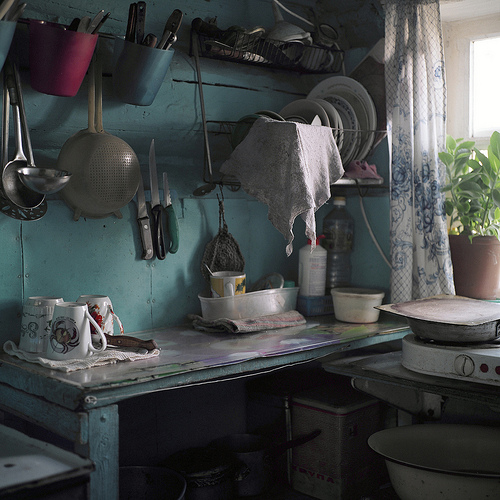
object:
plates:
[303, 71, 378, 173]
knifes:
[146, 134, 169, 263]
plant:
[437, 128, 499, 237]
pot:
[446, 232, 499, 301]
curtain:
[380, 1, 458, 309]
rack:
[207, 121, 387, 187]